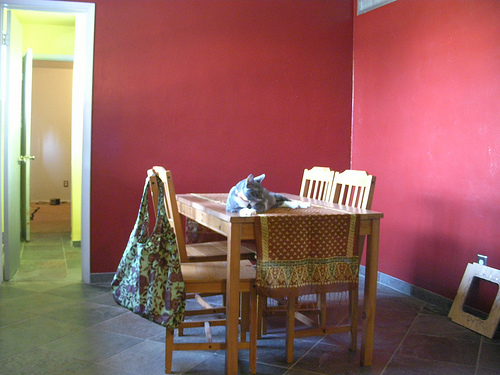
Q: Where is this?
A: This is at the dining room.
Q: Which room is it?
A: It is a dining room.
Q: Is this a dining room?
A: Yes, it is a dining room.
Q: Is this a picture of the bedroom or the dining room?
A: It is showing the dining room.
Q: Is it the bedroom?
A: No, it is the dining room.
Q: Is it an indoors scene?
A: Yes, it is indoors.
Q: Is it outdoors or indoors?
A: It is indoors.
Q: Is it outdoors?
A: No, it is indoors.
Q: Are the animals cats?
A: Yes, all the animals are cats.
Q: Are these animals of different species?
A: No, all the animals are cats.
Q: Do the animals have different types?
A: No, all the animals are cats.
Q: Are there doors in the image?
A: Yes, there is a door.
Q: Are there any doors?
A: Yes, there is a door.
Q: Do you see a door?
A: Yes, there is a door.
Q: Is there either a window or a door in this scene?
A: Yes, there is a door.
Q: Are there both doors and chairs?
A: Yes, there are both a door and a chair.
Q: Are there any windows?
A: No, there are no windows.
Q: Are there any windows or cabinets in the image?
A: No, there are no windows or cabinets.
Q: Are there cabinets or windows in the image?
A: No, there are no windows or cabinets.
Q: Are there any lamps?
A: No, there are no lamps.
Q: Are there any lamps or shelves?
A: No, there are no lamps or shelves.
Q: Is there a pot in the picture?
A: No, there are no pots.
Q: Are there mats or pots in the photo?
A: No, there are no pots or mats.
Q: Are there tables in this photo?
A: Yes, there is a table.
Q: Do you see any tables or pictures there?
A: Yes, there is a table.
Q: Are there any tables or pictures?
A: Yes, there is a table.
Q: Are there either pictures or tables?
A: Yes, there is a table.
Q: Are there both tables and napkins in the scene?
A: No, there is a table but no napkins.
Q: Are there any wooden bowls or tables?
A: Yes, there is a wood table.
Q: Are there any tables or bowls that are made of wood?
A: Yes, the table is made of wood.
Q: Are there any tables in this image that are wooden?
A: Yes, there is a wood table.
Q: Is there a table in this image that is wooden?
A: Yes, there is a table that is wooden.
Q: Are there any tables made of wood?
A: Yes, there is a table that is made of wood.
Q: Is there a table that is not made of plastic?
A: Yes, there is a table that is made of wood.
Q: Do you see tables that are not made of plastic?
A: Yes, there is a table that is made of wood.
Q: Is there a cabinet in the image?
A: No, there are no cabinets.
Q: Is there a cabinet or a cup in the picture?
A: No, there are no cabinets or cups.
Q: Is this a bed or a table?
A: This is a table.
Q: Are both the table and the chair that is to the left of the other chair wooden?
A: Yes, both the table and the chair are wooden.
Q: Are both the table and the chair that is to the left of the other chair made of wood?
A: Yes, both the table and the chair are made of wood.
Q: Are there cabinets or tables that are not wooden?
A: No, there is a table but it is wooden.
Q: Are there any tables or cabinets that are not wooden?
A: No, there is a table but it is wooden.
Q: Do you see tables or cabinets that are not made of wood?
A: No, there is a table but it is made of wood.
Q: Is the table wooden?
A: Yes, the table is wooden.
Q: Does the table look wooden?
A: Yes, the table is wooden.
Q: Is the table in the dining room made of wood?
A: Yes, the table is made of wood.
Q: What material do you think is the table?
A: The table is made of wood.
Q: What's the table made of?
A: The table is made of wood.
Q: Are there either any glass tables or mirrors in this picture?
A: No, there is a table but it is wooden.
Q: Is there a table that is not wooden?
A: No, there is a table but it is wooden.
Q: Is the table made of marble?
A: No, the table is made of wood.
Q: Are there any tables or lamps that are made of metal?
A: No, there is a table but it is made of wood.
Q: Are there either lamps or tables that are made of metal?
A: No, there is a table but it is made of wood.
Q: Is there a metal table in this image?
A: No, there is a table but it is made of wood.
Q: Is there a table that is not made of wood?
A: No, there is a table but it is made of wood.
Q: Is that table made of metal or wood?
A: The table is made of wood.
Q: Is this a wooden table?
A: Yes, this is a wooden table.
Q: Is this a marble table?
A: No, this is a wooden table.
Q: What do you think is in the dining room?
A: The table is in the dining room.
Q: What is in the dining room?
A: The table is in the dining room.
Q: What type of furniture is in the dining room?
A: The piece of furniture is a table.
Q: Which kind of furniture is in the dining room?
A: The piece of furniture is a table.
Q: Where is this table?
A: The table is in the dining room.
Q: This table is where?
A: The table is in the dining room.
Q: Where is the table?
A: The table is in the dining room.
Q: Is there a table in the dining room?
A: Yes, there is a table in the dining room.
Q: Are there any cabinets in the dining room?
A: No, there is a table in the dining room.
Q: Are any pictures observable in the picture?
A: No, there are no pictures.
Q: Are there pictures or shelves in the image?
A: No, there are no pictures or shelves.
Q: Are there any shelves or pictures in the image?
A: No, there are no pictures or shelves.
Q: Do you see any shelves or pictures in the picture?
A: No, there are no pictures or shelves.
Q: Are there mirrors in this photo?
A: No, there are no mirrors.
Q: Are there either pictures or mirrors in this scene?
A: No, there are no mirrors or pictures.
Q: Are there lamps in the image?
A: No, there are no lamps.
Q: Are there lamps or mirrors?
A: No, there are no lamps or mirrors.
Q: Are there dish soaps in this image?
A: No, there are no dish soaps.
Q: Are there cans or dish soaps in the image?
A: No, there are no dish soaps or cans.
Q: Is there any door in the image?
A: Yes, there is a door.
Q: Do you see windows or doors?
A: Yes, there is a door.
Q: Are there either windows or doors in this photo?
A: Yes, there is a door.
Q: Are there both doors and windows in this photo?
A: No, there is a door but no windows.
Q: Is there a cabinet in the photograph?
A: No, there are no cabinets.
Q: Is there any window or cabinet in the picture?
A: No, there are no cabinets or windows.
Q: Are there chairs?
A: Yes, there is a chair.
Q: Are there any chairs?
A: Yes, there is a chair.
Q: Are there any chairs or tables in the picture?
A: Yes, there is a chair.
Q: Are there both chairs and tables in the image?
A: Yes, there are both a chair and a table.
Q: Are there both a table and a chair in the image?
A: Yes, there are both a chair and a table.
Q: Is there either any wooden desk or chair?
A: Yes, there is a wood chair.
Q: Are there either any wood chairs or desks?
A: Yes, there is a wood chair.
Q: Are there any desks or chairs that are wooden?
A: Yes, the chair is wooden.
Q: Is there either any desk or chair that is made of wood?
A: Yes, the chair is made of wood.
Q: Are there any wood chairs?
A: Yes, there is a wood chair.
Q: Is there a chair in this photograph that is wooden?
A: Yes, there is a chair that is wooden.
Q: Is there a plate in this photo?
A: No, there are no plates.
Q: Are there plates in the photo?
A: No, there are no plates.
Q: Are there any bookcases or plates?
A: No, there are no plates or bookcases.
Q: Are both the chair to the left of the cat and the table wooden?
A: Yes, both the chair and the table are wooden.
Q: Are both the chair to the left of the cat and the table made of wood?
A: Yes, both the chair and the table are made of wood.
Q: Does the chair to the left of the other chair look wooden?
A: Yes, the chair is wooden.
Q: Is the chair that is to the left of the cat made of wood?
A: Yes, the chair is made of wood.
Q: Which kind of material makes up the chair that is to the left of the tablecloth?
A: The chair is made of wood.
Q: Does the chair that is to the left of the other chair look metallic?
A: No, the chair is wooden.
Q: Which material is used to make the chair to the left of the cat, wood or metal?
A: The chair is made of wood.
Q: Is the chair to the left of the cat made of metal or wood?
A: The chair is made of wood.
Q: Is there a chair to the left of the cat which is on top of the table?
A: Yes, there is a chair to the left of the cat.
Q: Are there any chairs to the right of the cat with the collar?
A: No, the chair is to the left of the cat.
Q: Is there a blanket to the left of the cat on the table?
A: No, there is a chair to the left of the cat.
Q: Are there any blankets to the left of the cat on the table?
A: No, there is a chair to the left of the cat.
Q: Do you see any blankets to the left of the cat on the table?
A: No, there is a chair to the left of the cat.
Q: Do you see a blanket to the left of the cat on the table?
A: No, there is a chair to the left of the cat.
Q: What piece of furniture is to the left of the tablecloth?
A: The piece of furniture is a chair.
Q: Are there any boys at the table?
A: No, there is a chair at the table.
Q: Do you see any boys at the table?
A: No, there is a chair at the table.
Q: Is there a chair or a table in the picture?
A: Yes, there is a chair.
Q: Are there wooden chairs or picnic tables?
A: Yes, there is a wood chair.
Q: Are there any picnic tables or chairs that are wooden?
A: Yes, the chair is wooden.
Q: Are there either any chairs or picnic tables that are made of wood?
A: Yes, the chair is made of wood.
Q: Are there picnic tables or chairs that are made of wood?
A: Yes, the chair is made of wood.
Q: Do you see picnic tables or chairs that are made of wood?
A: Yes, the chair is made of wood.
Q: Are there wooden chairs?
A: Yes, there is a wood chair.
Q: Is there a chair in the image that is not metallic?
A: Yes, there is a wooden chair.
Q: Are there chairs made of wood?
A: Yes, there is a chair that is made of wood.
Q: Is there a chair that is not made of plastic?
A: Yes, there is a chair that is made of wood.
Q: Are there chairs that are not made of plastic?
A: Yes, there is a chair that is made of wood.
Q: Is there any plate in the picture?
A: No, there are no plates.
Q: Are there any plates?
A: No, there are no plates.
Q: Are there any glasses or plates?
A: No, there are no plates or glasses.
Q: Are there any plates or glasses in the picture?
A: No, there are no plates or glasses.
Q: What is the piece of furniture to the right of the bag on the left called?
A: The piece of furniture is a chair.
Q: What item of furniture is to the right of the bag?
A: The piece of furniture is a chair.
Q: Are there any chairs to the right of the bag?
A: Yes, there is a chair to the right of the bag.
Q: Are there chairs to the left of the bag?
A: No, the chair is to the right of the bag.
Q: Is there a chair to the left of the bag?
A: No, the chair is to the right of the bag.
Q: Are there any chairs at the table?
A: Yes, there is a chair at the table.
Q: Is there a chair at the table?
A: Yes, there is a chair at the table.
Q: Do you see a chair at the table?
A: Yes, there is a chair at the table.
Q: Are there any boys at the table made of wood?
A: No, there is a chair at the table.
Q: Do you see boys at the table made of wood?
A: No, there is a chair at the table.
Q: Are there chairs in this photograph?
A: Yes, there is a chair.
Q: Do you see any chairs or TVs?
A: Yes, there is a chair.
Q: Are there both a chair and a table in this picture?
A: Yes, there are both a chair and a table.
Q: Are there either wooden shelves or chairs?
A: Yes, there is a wood chair.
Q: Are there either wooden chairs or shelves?
A: Yes, there is a wood chair.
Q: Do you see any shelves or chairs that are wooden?
A: Yes, the chair is wooden.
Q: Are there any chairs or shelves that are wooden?
A: Yes, the chair is wooden.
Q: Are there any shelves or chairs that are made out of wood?
A: Yes, the chair is made of wood.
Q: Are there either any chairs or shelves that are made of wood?
A: Yes, the chair is made of wood.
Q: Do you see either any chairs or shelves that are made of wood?
A: Yes, the chair is made of wood.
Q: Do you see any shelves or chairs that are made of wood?
A: Yes, the chair is made of wood.